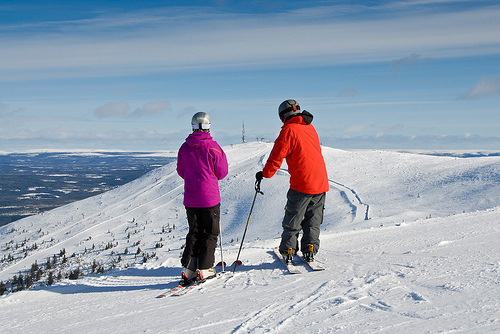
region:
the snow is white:
[338, 252, 393, 314]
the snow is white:
[364, 231, 376, 261]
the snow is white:
[332, 300, 347, 318]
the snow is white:
[354, 302, 376, 324]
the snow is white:
[392, 209, 464, 331]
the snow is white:
[388, 250, 433, 331]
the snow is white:
[382, 275, 390, 322]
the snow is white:
[376, 261, 407, 327]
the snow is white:
[385, 266, 400, 329]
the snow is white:
[356, 260, 443, 325]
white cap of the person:
[176, 102, 218, 132]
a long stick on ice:
[224, 182, 269, 289]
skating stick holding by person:
[222, 186, 274, 287]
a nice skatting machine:
[265, 230, 326, 278]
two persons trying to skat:
[131, 103, 397, 296]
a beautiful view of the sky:
[26, 15, 498, 150]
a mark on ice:
[318, 160, 379, 240]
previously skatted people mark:
[336, 167, 384, 252]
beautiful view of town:
[17, 147, 172, 224]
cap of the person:
[281, 99, 307, 112]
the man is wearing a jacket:
[259, 110, 334, 200]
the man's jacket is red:
[266, 107, 333, 197]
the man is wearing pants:
[275, 187, 330, 264]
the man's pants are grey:
[279, 185, 329, 262]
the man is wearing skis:
[269, 246, 327, 284]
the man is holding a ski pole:
[231, 171, 263, 268]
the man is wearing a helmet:
[276, 94, 303, 122]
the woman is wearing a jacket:
[173, 129, 237, 214]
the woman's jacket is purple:
[172, 127, 231, 217]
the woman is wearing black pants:
[176, 201, 226, 276]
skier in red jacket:
[271, 91, 343, 265]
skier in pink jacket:
[151, 105, 224, 302]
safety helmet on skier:
[270, 92, 310, 118]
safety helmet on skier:
[193, 110, 210, 137]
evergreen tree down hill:
[131, 245, 144, 253]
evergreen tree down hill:
[70, 266, 84, 283]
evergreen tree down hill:
[44, 248, 64, 263]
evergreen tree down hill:
[20, 277, 30, 287]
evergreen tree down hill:
[7, 275, 14, 285]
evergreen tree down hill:
[137, 251, 152, 261]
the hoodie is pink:
[171, 134, 231, 209]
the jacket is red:
[268, 111, 330, 206]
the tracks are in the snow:
[336, 178, 373, 234]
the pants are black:
[163, 197, 233, 273]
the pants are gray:
[277, 188, 329, 257]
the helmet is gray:
[278, 92, 308, 117]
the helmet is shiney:
[188, 107, 211, 125]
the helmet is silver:
[188, 105, 214, 126]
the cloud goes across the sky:
[69, 23, 421, 83]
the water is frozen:
[26, 148, 109, 191]